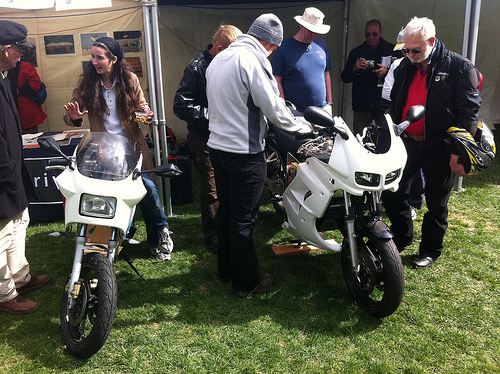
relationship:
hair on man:
[398, 11, 438, 59] [384, 5, 498, 269]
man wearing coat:
[384, 6, 474, 277] [388, 40, 483, 156]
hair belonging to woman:
[73, 36, 135, 118] [61, 33, 174, 253]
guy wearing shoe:
[0, 20, 52, 315] [1, 294, 41, 314]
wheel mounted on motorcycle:
[337, 215, 405, 318] [264, 102, 426, 318]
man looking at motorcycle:
[204, 13, 312, 298] [264, 102, 426, 318]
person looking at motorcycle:
[170, 21, 244, 254] [264, 102, 426, 318]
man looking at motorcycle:
[271, 6, 334, 132] [264, 102, 426, 318]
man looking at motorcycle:
[380, 16, 496, 270] [264, 102, 426, 318]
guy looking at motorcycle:
[340, 19, 405, 138] [264, 102, 426, 318]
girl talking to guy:
[61, 33, 173, 256] [1, 20, 51, 314]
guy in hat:
[0, 21, 58, 277] [3, 14, 52, 54]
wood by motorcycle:
[261, 231, 323, 252] [269, 104, 399, 267]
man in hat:
[280, 8, 363, 174] [287, 5, 338, 44]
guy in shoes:
[0, 20, 52, 315] [5, 267, 45, 308]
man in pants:
[165, 21, 307, 280] [168, 147, 252, 302]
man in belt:
[361, 21, 437, 264] [396, 115, 459, 172]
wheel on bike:
[68, 260, 128, 336] [19, 112, 175, 296]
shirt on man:
[392, 65, 440, 147] [392, 30, 478, 240]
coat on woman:
[122, 77, 179, 156] [52, 39, 175, 197]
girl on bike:
[63, 37, 174, 262] [36, 131, 182, 358]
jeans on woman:
[117, 166, 189, 248] [54, 36, 175, 247]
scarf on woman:
[84, 63, 149, 103] [59, 33, 172, 223]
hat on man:
[0, 25, 54, 97] [5, 24, 49, 294]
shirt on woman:
[85, 99, 142, 144] [46, 9, 155, 169]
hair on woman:
[95, 32, 141, 84] [74, 40, 187, 212]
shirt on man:
[400, 64, 427, 135] [381, 25, 494, 240]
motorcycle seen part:
[276, 86, 421, 342] [313, 140, 362, 189]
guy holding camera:
[337, 13, 409, 143] [362, 54, 380, 67]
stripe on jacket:
[245, 97, 262, 152] [202, 33, 311, 153]